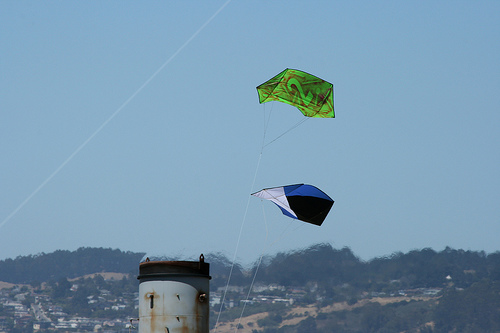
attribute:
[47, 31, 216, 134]
sky — blue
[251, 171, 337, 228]
kite — black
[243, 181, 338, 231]
kite — blue, white and black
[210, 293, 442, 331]
hill — brown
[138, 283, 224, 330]
pole — grey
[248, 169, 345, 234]
kite — white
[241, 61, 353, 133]
kite — green